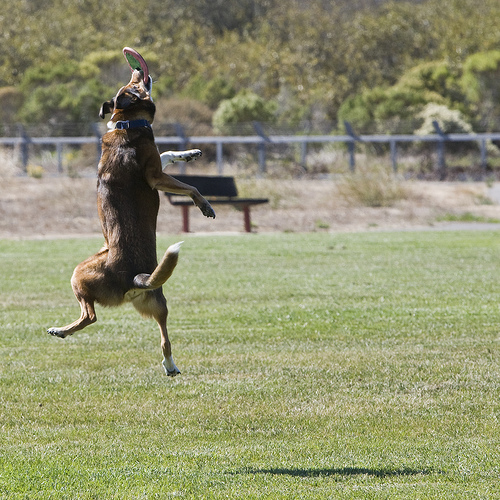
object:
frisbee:
[124, 47, 152, 82]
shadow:
[222, 466, 453, 480]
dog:
[47, 85, 218, 379]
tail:
[135, 242, 181, 294]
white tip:
[168, 240, 182, 257]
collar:
[107, 119, 154, 129]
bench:
[0, 159, 500, 235]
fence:
[1, 128, 497, 181]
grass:
[0, 231, 499, 500]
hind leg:
[47, 254, 123, 338]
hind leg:
[130, 293, 181, 376]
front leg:
[160, 150, 201, 163]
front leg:
[142, 171, 216, 219]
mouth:
[134, 70, 153, 90]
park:
[2, 1, 499, 500]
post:
[183, 205, 190, 235]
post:
[245, 208, 252, 233]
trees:
[1, 1, 500, 133]